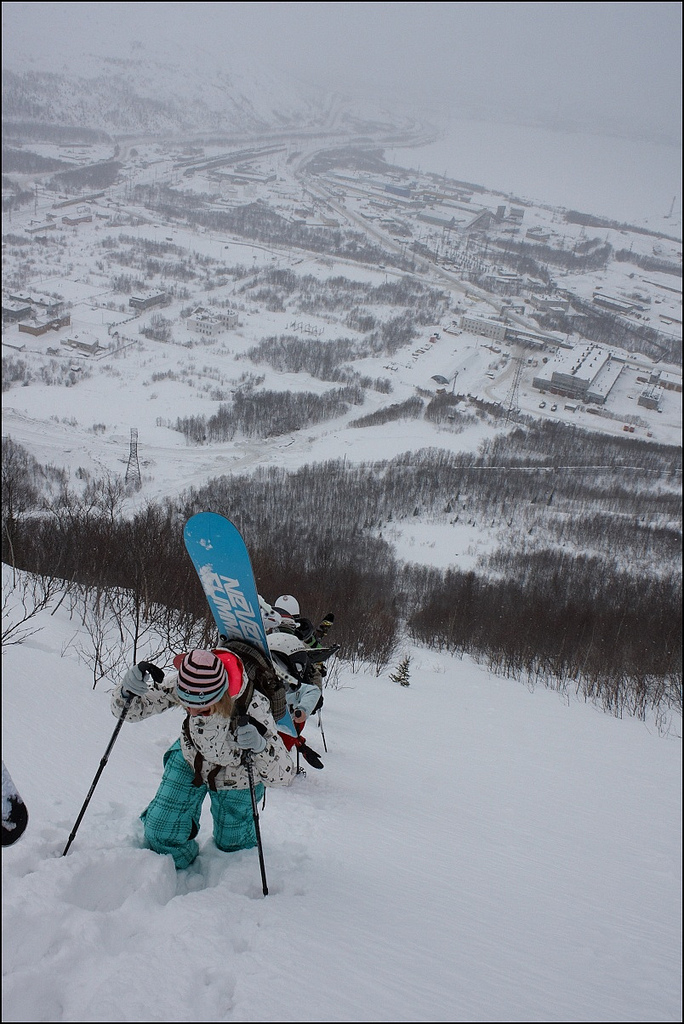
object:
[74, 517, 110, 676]
trees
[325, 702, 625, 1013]
snow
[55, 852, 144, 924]
foot steps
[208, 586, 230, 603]
letter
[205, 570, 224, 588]
letter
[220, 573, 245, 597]
letter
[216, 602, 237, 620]
letter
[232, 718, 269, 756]
glove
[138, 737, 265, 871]
pants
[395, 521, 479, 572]
clearing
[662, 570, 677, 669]
trees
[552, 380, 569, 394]
wall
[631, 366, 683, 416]
building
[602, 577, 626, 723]
shrub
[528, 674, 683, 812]
ground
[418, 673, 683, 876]
ground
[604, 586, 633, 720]
shrub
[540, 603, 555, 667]
shrub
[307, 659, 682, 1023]
ground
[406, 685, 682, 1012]
ground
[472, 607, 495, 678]
shrub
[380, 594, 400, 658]
shrub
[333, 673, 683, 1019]
ground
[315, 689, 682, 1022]
ground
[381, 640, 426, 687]
shrub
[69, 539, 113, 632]
shrub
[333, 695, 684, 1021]
ground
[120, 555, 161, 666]
shrub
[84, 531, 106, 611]
shrub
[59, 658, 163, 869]
ski poles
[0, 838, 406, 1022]
snow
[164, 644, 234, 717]
knit cap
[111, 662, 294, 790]
jacket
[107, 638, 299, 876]
woman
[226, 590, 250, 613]
lettering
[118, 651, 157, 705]
glove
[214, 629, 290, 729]
backpack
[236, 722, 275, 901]
ski poles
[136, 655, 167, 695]
strap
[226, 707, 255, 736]
strap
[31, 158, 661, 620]
mountainside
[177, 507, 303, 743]
snowboard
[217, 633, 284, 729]
back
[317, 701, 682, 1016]
hill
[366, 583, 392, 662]
trees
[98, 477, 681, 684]
ravine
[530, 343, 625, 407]
building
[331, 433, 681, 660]
valley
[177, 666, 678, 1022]
hill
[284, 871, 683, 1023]
snow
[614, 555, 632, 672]
trees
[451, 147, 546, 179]
snow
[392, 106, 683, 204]
water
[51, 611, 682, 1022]
hill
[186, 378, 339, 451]
forest patch